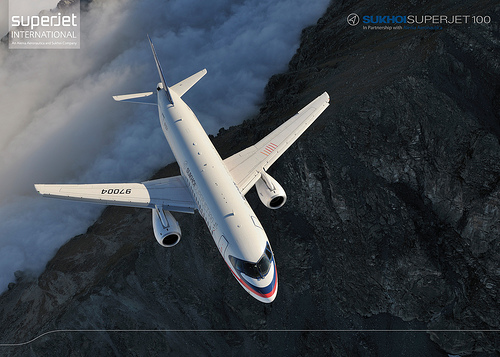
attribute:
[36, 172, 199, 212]
wing — white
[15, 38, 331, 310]
plane — blue, red, white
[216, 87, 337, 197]
wing — white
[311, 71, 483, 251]
mountain — gray, beautiful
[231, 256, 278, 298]
front — white, red, blue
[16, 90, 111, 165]
clouds — white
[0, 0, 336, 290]
cloud — white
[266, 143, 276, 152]
stripe — red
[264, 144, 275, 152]
stripe — red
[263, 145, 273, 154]
stripe — red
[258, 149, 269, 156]
stripe — red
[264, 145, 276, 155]
stripe — red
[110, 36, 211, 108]
tail — top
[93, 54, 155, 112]
wing — end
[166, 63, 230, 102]
wing — end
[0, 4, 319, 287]
clouds — white